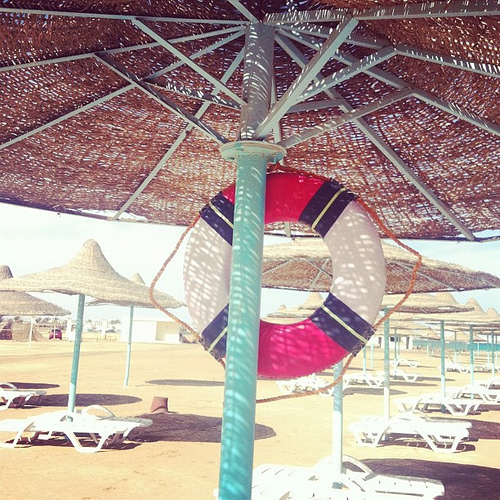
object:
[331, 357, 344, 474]
pole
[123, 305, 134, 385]
pole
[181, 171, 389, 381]
life saver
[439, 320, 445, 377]
blue pole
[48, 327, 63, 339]
car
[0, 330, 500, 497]
ground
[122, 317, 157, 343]
wall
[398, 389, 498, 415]
chair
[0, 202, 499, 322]
sky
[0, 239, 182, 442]
umbrella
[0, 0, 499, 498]
umbrella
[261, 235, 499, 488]
umbrella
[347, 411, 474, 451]
beach chair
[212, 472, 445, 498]
beach chair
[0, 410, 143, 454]
beach chair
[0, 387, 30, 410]
beach chair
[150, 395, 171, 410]
barrel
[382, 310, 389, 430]
pole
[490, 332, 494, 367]
pole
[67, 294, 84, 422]
pole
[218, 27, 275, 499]
pole